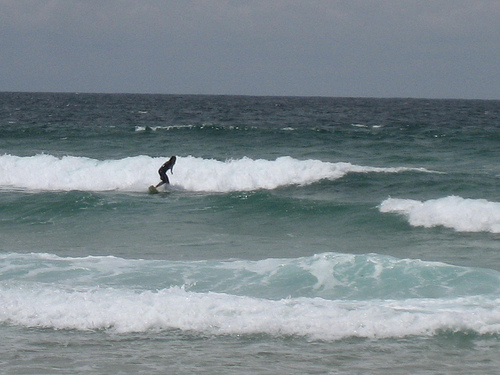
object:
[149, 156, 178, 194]
man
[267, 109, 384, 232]
water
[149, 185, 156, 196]
surfboard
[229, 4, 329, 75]
sky